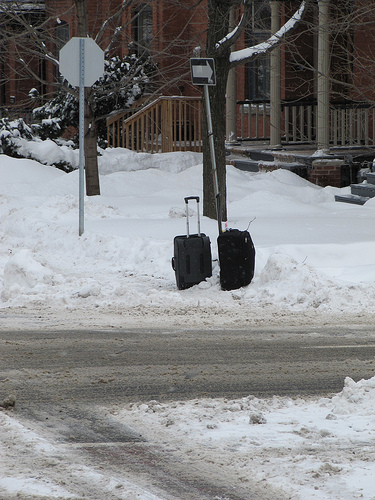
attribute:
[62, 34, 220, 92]
sign — street, white, stop, one-way, light colored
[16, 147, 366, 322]
snow — white, snow-covered, dark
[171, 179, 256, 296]
luggage — grey, black, sitting, gray, small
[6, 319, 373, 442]
street — plowed, snowy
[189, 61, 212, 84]
arrow — white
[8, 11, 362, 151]
bushes — green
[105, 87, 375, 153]
railing — wooden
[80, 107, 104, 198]
trunk — tree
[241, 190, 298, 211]
mountain — small, of snow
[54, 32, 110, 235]
sign — stop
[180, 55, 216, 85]
sign — arrow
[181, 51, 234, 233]
sign — street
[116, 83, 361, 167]
porch — building's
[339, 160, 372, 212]
stairs — building's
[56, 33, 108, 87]
sign — octoganol , street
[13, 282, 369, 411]
road — slushy